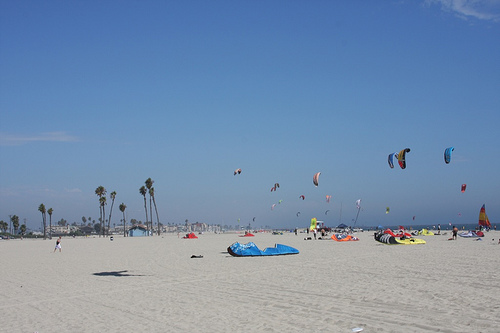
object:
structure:
[331, 233, 360, 241]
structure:
[227, 241, 299, 257]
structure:
[183, 232, 198, 239]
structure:
[238, 230, 254, 236]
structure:
[374, 225, 426, 245]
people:
[54, 236, 62, 253]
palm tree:
[145, 177, 155, 236]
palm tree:
[139, 186, 150, 237]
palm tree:
[119, 202, 128, 237]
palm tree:
[94, 185, 107, 238]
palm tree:
[47, 208, 54, 240]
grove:
[1, 177, 161, 240]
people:
[452, 225, 459, 239]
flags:
[387, 148, 410, 170]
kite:
[227, 241, 300, 256]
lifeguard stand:
[309, 217, 316, 232]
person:
[313, 228, 317, 240]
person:
[438, 224, 441, 234]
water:
[413, 225, 435, 230]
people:
[293, 228, 297, 236]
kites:
[253, 217, 256, 222]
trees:
[185, 219, 189, 228]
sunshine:
[0, 0, 500, 331]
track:
[325, 305, 377, 322]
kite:
[398, 148, 411, 170]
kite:
[234, 168, 242, 176]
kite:
[385, 206, 390, 213]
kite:
[312, 172, 321, 187]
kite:
[461, 183, 467, 193]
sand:
[0, 228, 500, 333]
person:
[321, 229, 326, 238]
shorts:
[453, 231, 458, 236]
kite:
[183, 232, 198, 239]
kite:
[388, 151, 399, 168]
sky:
[0, 1, 498, 231]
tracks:
[0, 276, 216, 324]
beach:
[0, 229, 500, 333]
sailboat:
[479, 203, 492, 227]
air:
[0, 0, 495, 198]